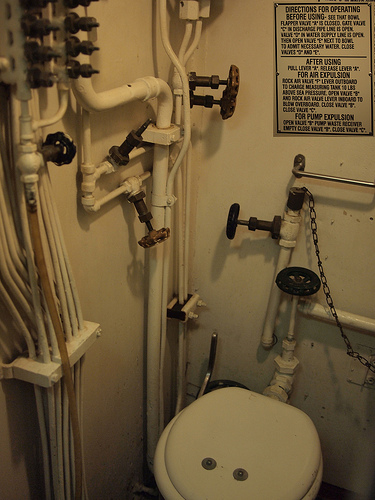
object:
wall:
[178, 0, 375, 495]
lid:
[164, 385, 322, 474]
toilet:
[150, 380, 327, 500]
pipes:
[278, 247, 293, 257]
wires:
[312, 218, 317, 231]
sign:
[271, 0, 375, 140]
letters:
[305, 58, 309, 65]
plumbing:
[0, 0, 375, 477]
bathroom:
[0, 0, 375, 498]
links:
[359, 357, 370, 367]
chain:
[298, 186, 375, 377]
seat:
[152, 385, 324, 499]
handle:
[192, 328, 220, 401]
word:
[305, 57, 323, 66]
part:
[238, 406, 257, 418]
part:
[53, 150, 75, 158]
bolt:
[16, 129, 79, 183]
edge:
[261, 395, 269, 398]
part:
[279, 460, 308, 485]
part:
[239, 7, 260, 16]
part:
[117, 16, 126, 22]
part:
[331, 144, 338, 151]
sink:
[273, 263, 322, 299]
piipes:
[106, 90, 117, 111]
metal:
[210, 361, 215, 365]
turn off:
[287, 186, 306, 210]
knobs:
[125, 185, 172, 250]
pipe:
[146, 189, 167, 334]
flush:
[150, 384, 326, 500]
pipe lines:
[148, 280, 163, 295]